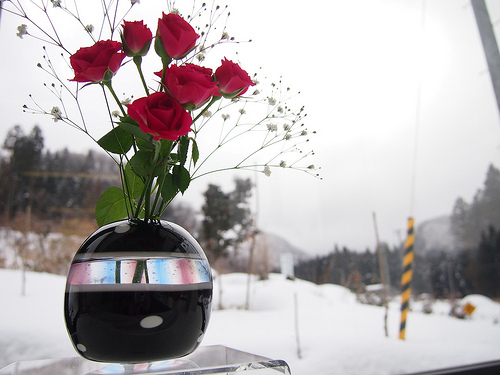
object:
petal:
[89, 49, 114, 63]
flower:
[68, 38, 127, 90]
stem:
[107, 73, 128, 117]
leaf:
[98, 121, 139, 154]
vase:
[63, 217, 214, 363]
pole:
[397, 200, 416, 339]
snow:
[0, 270, 500, 374]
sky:
[0, 0, 500, 272]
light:
[100, 228, 129, 252]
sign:
[462, 294, 480, 317]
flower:
[247, 117, 293, 149]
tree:
[459, 225, 498, 300]